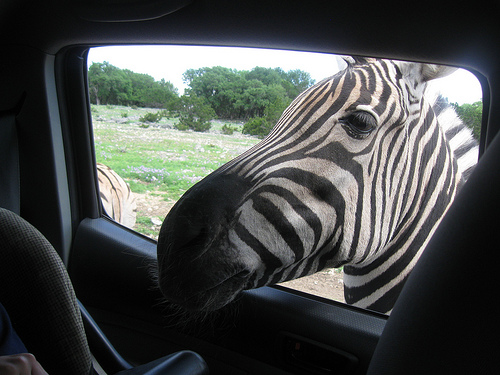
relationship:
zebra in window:
[190, 86, 470, 296] [66, 47, 443, 314]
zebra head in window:
[152, 54, 481, 323] [39, 30, 493, 341]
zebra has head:
[156, 53, 480, 317] [148, 58, 446, 319]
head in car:
[148, 58, 446, 319] [5, 8, 493, 368]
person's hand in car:
[1, 348, 46, 372] [5, 8, 493, 368]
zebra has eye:
[156, 53, 480, 317] [339, 107, 379, 139]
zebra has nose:
[156, 53, 480, 317] [155, 192, 228, 274]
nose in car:
[155, 192, 228, 274] [5, 8, 493, 368]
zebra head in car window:
[152, 54, 481, 323] [36, 36, 495, 329]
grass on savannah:
[133, 139, 184, 175] [128, 65, 228, 125]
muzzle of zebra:
[159, 214, 240, 304] [154, 68, 460, 331]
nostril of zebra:
[186, 215, 221, 249] [156, 53, 480, 317]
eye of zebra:
[343, 110, 377, 138] [161, 61, 484, 276]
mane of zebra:
[422, 83, 479, 181] [167, 63, 473, 349]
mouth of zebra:
[164, 263, 250, 313] [143, 72, 472, 295]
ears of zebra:
[336, 55, 452, 87] [156, 53, 480, 317]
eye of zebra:
[343, 110, 377, 138] [154, 68, 468, 307]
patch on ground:
[131, 166, 165, 175] [94, 100, 237, 237]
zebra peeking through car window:
[156, 53, 480, 317] [83, 41, 483, 318]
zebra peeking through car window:
[156, 53, 480, 317] [86, 45, 482, 318]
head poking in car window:
[156, 53, 459, 310] [86, 45, 482, 318]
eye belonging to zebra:
[343, 110, 377, 138] [156, 53, 480, 317]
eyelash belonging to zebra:
[355, 110, 376, 127] [156, 53, 480, 317]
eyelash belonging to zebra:
[365, 110, 369, 127] [156, 53, 480, 317]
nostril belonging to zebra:
[178, 215, 213, 252] [156, 53, 480, 317]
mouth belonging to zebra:
[164, 263, 250, 313] [156, 53, 480, 317]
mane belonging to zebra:
[422, 83, 479, 181] [156, 53, 480, 317]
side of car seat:
[2, 209, 92, 372] [0, 208, 206, 372]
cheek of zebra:
[335, 166, 385, 261] [156, 53, 480, 317]